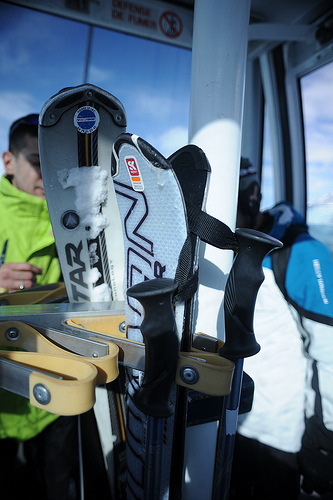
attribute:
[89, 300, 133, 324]
ski — grey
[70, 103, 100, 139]
tag — small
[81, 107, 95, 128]
tag — small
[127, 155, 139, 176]
box — red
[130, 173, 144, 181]
box — orange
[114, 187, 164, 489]
writing — black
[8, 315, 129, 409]
straps — tan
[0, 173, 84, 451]
jacket — green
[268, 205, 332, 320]
jacket — blue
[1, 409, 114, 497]
color — black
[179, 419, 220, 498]
color — gray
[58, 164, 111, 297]
snow — white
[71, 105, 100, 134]
border — white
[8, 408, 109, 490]
pants — black 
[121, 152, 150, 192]
sticker — blue 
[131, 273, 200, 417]
handle — black 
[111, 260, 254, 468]
pole — ski 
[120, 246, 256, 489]
pole — ski 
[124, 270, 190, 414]
handle — rubber 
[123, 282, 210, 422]
grip — ski pole  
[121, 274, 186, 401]
grip — black ski poke 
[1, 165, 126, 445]
jacket —  neon green , green 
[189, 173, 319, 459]
jacket —  white ,  blue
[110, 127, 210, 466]
skis — SET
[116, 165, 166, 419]
writing — BLACK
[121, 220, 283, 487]
poles — SET, SKI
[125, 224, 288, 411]
handles — BLACK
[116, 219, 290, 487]
ski poles — SILVER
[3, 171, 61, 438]
jacket — neon yellow, winter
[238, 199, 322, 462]
coat — winter, blue, white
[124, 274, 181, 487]
ski pole — black handled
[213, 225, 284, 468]
ski pole — black handled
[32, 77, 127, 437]
ski — reflective, grey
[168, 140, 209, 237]
bottom — black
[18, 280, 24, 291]
ring — man's, silver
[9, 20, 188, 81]
sky — cloudy, blue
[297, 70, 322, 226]
sky — blue, cloudy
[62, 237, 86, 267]
letter — R